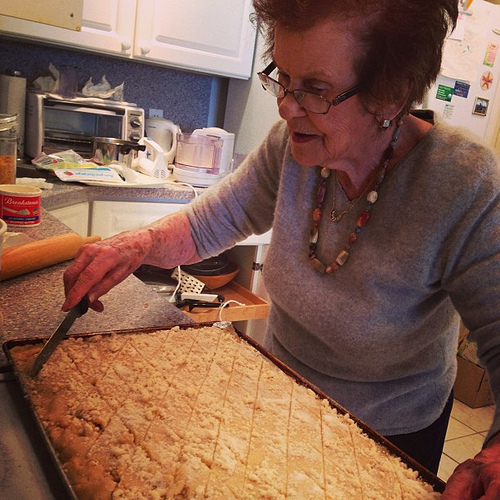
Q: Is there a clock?
A: No, there are no clocks.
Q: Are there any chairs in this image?
A: No, there are no chairs.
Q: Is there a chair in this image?
A: No, there are no chairs.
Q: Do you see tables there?
A: No, there are no tables.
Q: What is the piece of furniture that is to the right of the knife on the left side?
A: The piece of furniture is a shelf.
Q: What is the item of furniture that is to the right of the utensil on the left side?
A: The piece of furniture is a shelf.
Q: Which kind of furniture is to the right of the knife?
A: The piece of furniture is a shelf.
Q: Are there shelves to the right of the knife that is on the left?
A: Yes, there is a shelf to the right of the knife.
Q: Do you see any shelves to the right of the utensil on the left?
A: Yes, there is a shelf to the right of the knife.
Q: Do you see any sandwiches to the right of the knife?
A: No, there is a shelf to the right of the knife.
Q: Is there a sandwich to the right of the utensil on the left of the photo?
A: No, there is a shelf to the right of the knife.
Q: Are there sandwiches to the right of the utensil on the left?
A: No, there is a shelf to the right of the knife.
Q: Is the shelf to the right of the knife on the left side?
A: Yes, the shelf is to the right of the knife.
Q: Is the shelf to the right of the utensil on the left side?
A: Yes, the shelf is to the right of the knife.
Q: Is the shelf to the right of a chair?
A: No, the shelf is to the right of the knife.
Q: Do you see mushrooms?
A: No, there are no mushrooms.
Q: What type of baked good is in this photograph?
A: The baked good is a pastry.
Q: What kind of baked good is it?
A: The food is a pastry.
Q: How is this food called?
A: That is a pastry.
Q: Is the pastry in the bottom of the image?
A: Yes, the pastry is in the bottom of the image.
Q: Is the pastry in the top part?
A: No, the pastry is in the bottom of the image.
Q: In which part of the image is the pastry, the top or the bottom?
A: The pastry is in the bottom of the image.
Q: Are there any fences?
A: No, there are no fences.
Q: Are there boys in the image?
A: No, there are no boys.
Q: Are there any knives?
A: Yes, there is a knife.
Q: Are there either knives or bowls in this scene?
A: Yes, there is a knife.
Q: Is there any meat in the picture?
A: No, there is no meat.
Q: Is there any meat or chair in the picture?
A: No, there are no meat or chairs.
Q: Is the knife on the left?
A: Yes, the knife is on the left of the image.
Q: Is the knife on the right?
A: No, the knife is on the left of the image.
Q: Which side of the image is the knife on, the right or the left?
A: The knife is on the left of the image.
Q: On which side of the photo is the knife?
A: The knife is on the left of the image.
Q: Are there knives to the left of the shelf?
A: Yes, there is a knife to the left of the shelf.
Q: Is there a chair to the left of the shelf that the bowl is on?
A: No, there is a knife to the left of the shelf.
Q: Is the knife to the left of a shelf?
A: Yes, the knife is to the left of a shelf.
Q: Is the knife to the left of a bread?
A: No, the knife is to the left of a shelf.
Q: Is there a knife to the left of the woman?
A: Yes, there is a knife to the left of the woman.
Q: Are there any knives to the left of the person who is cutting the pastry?
A: Yes, there is a knife to the left of the woman.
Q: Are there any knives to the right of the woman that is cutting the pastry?
A: No, the knife is to the left of the woman.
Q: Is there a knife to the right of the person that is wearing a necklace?
A: No, the knife is to the left of the woman.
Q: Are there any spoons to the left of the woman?
A: No, there is a knife to the left of the woman.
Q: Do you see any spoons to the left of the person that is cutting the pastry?
A: No, there is a knife to the left of the woman.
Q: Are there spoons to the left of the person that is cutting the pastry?
A: No, there is a knife to the left of the woman.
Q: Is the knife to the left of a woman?
A: Yes, the knife is to the left of a woman.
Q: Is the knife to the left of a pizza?
A: No, the knife is to the left of a woman.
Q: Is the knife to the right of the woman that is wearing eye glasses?
A: No, the knife is to the left of the woman.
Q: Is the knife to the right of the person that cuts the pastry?
A: No, the knife is to the left of the woman.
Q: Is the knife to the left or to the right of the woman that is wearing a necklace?
A: The knife is to the left of the woman.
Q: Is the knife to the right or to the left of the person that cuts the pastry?
A: The knife is to the left of the woman.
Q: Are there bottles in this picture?
A: No, there are no bottles.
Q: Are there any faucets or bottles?
A: No, there are no bottles or faucets.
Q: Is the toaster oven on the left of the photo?
A: Yes, the toaster oven is on the left of the image.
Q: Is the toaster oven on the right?
A: No, the toaster oven is on the left of the image.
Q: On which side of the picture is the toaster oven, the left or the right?
A: The toaster oven is on the left of the image.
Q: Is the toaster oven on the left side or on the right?
A: The toaster oven is on the left of the image.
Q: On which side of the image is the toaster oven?
A: The toaster oven is on the left of the image.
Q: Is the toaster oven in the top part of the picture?
A: Yes, the toaster oven is in the top of the image.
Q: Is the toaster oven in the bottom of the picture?
A: No, the toaster oven is in the top of the image.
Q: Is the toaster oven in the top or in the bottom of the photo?
A: The toaster oven is in the top of the image.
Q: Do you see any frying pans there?
A: No, there are no frying pans.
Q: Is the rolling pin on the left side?
A: Yes, the rolling pin is on the left of the image.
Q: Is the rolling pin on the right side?
A: No, the rolling pin is on the left of the image.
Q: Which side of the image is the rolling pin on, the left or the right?
A: The rolling pin is on the left of the image.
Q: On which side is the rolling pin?
A: The rolling pin is on the left of the image.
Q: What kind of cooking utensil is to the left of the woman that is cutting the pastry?
A: The cooking utensil is a rolling pin.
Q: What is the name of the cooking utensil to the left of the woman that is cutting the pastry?
A: The cooking utensil is a rolling pin.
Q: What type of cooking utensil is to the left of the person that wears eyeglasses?
A: The cooking utensil is a rolling pin.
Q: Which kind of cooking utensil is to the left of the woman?
A: The cooking utensil is a rolling pin.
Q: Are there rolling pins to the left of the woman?
A: Yes, there is a rolling pin to the left of the woman.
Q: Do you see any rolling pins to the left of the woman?
A: Yes, there is a rolling pin to the left of the woman.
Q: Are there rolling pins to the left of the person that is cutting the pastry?
A: Yes, there is a rolling pin to the left of the woman.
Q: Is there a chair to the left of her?
A: No, there is a rolling pin to the left of the woman.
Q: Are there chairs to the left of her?
A: No, there is a rolling pin to the left of the woman.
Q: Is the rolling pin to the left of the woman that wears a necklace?
A: Yes, the rolling pin is to the left of the woman.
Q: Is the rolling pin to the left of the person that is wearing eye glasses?
A: Yes, the rolling pin is to the left of the woman.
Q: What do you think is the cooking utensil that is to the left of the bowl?
A: The cooking utensil is a rolling pin.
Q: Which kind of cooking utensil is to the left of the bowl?
A: The cooking utensil is a rolling pin.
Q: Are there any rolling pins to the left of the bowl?
A: Yes, there is a rolling pin to the left of the bowl.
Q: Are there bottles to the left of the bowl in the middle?
A: No, there is a rolling pin to the left of the bowl.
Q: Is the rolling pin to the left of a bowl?
A: Yes, the rolling pin is to the left of a bowl.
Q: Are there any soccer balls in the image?
A: No, there are no soccer balls.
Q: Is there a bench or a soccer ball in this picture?
A: No, there are no soccer balls or benches.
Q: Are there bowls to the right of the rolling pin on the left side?
A: Yes, there is a bowl to the right of the rolling pin.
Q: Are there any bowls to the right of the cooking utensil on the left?
A: Yes, there is a bowl to the right of the rolling pin.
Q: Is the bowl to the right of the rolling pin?
A: Yes, the bowl is to the right of the rolling pin.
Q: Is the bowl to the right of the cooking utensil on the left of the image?
A: Yes, the bowl is to the right of the rolling pin.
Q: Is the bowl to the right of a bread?
A: No, the bowl is to the right of the rolling pin.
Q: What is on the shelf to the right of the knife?
A: The bowl is on the shelf.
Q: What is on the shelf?
A: The bowl is on the shelf.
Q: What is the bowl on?
A: The bowl is on the shelf.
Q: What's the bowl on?
A: The bowl is on the shelf.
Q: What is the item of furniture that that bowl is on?
A: The piece of furniture is a shelf.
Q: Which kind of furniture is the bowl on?
A: The bowl is on the shelf.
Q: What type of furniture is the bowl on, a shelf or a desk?
A: The bowl is on a shelf.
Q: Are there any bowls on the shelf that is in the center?
A: Yes, there is a bowl on the shelf.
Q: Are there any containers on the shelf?
A: No, there is a bowl on the shelf.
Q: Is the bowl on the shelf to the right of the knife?
A: Yes, the bowl is on the shelf.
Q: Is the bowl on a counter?
A: No, the bowl is on the shelf.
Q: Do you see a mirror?
A: No, there are no mirrors.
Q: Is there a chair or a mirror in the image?
A: No, there are no mirrors or chairs.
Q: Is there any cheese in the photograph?
A: No, there is no cheese.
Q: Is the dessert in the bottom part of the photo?
A: Yes, the dessert is in the bottom of the image.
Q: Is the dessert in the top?
A: No, the dessert is in the bottom of the image.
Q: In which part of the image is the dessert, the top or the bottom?
A: The dessert is in the bottom of the image.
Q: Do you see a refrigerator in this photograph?
A: Yes, there is a refrigerator.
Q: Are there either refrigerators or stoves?
A: Yes, there is a refrigerator.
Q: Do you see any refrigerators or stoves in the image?
A: Yes, there is a refrigerator.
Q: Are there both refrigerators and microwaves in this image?
A: No, there is a refrigerator but no microwaves.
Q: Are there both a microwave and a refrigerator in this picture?
A: No, there is a refrigerator but no microwaves.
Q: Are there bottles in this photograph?
A: No, there are no bottles.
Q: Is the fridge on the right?
A: Yes, the fridge is on the right of the image.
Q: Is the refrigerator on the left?
A: No, the refrigerator is on the right of the image.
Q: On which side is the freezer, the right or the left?
A: The freezer is on the right of the image.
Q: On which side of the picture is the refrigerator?
A: The refrigerator is on the right of the image.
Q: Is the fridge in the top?
A: Yes, the fridge is in the top of the image.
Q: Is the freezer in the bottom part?
A: No, the freezer is in the top of the image.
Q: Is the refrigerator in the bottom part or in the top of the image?
A: The refrigerator is in the top of the image.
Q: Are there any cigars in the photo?
A: No, there are no cigars.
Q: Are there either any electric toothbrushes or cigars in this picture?
A: No, there are no cigars or electric toothbrushes.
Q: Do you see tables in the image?
A: No, there are no tables.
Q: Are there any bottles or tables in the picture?
A: No, there are no tables or bottles.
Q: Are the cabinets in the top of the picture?
A: Yes, the cabinets are in the top of the image.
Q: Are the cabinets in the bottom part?
A: No, the cabinets are in the top of the image.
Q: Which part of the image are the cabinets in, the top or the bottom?
A: The cabinets are in the top of the image.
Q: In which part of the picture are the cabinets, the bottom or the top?
A: The cabinets are in the top of the image.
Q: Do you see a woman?
A: Yes, there is a woman.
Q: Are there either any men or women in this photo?
A: Yes, there is a woman.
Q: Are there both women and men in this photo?
A: No, there is a woman but no men.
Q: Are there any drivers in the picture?
A: No, there are no drivers.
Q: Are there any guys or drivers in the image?
A: No, there are no drivers or guys.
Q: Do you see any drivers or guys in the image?
A: No, there are no drivers or guys.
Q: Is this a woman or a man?
A: This is a woman.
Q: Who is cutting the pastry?
A: The woman is cutting the pastry.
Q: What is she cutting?
A: The woman is cutting the pastry.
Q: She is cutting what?
A: The woman is cutting the pastry.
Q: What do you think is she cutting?
A: The woman is cutting the pastry.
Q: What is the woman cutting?
A: The woman is cutting the pastry.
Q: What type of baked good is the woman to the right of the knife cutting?
A: The woman is cutting the pastry.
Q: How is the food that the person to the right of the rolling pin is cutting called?
A: The food is a pastry.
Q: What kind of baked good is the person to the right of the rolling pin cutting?
A: The woman is cutting the pastry.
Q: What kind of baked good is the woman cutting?
A: The woman is cutting the pastry.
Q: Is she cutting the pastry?
A: Yes, the woman is cutting the pastry.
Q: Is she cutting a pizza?
A: No, the woman is cutting the pastry.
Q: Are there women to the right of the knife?
A: Yes, there is a woman to the right of the knife.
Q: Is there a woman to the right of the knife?
A: Yes, there is a woman to the right of the knife.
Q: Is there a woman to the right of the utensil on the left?
A: Yes, there is a woman to the right of the knife.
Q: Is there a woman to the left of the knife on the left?
A: No, the woman is to the right of the knife.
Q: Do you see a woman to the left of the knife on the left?
A: No, the woman is to the right of the knife.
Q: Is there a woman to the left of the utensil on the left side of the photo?
A: No, the woman is to the right of the knife.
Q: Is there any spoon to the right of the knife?
A: No, there is a woman to the right of the knife.